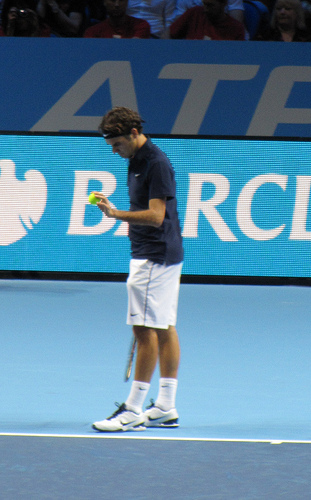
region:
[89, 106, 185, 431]
An athlete holding a tennis racket and ball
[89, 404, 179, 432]
A pair of white and back shoes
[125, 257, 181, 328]
A pair of white shorts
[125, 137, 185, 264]
A shirt on a male athlete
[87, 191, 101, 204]
A bright, green tennis ball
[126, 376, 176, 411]
Nike brand athletic socks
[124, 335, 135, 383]
A tennis racket in a man's hand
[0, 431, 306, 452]
White line on a blue court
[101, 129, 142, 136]
Black headband on a man's head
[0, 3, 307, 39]
People in a crowd watching tennis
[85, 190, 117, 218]
man holding yellow tennis ball in hand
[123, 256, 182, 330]
man carries tennis ball in his pants pocket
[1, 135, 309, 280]
sponsor sign in back of tennis court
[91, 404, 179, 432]
man wearing white nike shoes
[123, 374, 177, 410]
man wearing white nike socks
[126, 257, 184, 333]
man wearing white nike short pants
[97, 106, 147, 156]
player wearing dark blue headband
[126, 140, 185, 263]
man wearing dark blue polo shirt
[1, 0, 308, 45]
people watching game in the distance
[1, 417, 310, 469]
ground made of light and dark blue surfaces, and white lines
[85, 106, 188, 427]
man wearing blue shirt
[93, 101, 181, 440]
man wearing white shorts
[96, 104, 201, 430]
man wearing white socks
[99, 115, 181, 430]
man wearing white shoes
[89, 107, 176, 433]
man holding a racket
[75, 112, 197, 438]
man holding a ball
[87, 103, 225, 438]
man standing on a court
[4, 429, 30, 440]
line on a court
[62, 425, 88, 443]
line on a court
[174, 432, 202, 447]
line on a court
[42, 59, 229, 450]
a professional tennis player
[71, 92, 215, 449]
a male professional tennis player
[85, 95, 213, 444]
a player about to serve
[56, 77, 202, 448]
a player about to bounce the ball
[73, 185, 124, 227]
a hand holding a tennis ball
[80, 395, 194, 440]
a pair of Nike tennis shoes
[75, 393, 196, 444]
a pair of white and black tennis shoes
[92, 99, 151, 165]
the head of a tennis player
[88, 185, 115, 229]
the hand of a tennis player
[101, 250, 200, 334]
a pair of white tennis shorts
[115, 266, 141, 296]
tennis ball bulge in white short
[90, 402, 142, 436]
black and white shoe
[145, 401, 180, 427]
black and white shoe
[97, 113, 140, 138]
black and white headband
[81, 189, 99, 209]
neon green tennis ball in man's hand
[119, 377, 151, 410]
white socks with black nike logo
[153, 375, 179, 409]
white socks with black nike logo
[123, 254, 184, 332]
black and white shorts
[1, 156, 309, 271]
white logo on blue wall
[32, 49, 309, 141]
white logo on blue wall